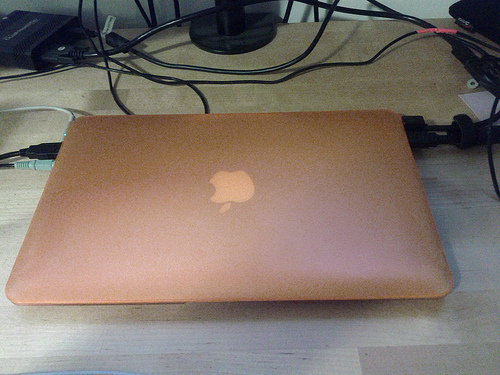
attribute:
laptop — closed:
[59, 115, 420, 311]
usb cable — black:
[18, 137, 77, 166]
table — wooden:
[243, 294, 499, 373]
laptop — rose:
[62, 120, 420, 335]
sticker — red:
[413, 22, 463, 41]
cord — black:
[188, 26, 416, 87]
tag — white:
[99, 14, 117, 40]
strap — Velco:
[446, 108, 478, 153]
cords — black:
[147, 45, 352, 90]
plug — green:
[9, 156, 56, 174]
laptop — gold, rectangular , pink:
[6, 109, 456, 306]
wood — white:
[170, 331, 372, 373]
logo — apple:
[204, 167, 260, 214]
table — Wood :
[5, 9, 491, 372]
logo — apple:
[202, 166, 256, 213]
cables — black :
[1, 6, 498, 169]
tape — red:
[412, 20, 461, 39]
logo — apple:
[210, 169, 255, 215]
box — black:
[0, 9, 85, 72]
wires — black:
[2, 1, 499, 197]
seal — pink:
[415, 24, 457, 35]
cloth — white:
[3, 20, 499, 372]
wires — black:
[3, 2, 499, 124]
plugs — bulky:
[401, 109, 499, 153]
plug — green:
[3, 156, 54, 172]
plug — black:
[3, 142, 61, 157]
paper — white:
[455, 89, 498, 119]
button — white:
[465, 77, 481, 90]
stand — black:
[187, 2, 280, 54]